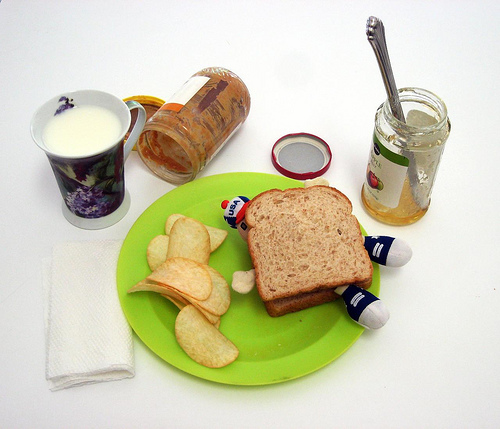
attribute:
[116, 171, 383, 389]
plate — green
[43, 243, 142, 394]
napkin — white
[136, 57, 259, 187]
jar — empty, labeled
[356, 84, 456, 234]
jar — empty, labeled, glass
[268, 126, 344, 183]
lid — red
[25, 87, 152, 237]
mug — filled, tall, purple, full, floral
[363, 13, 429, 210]
knife — silver